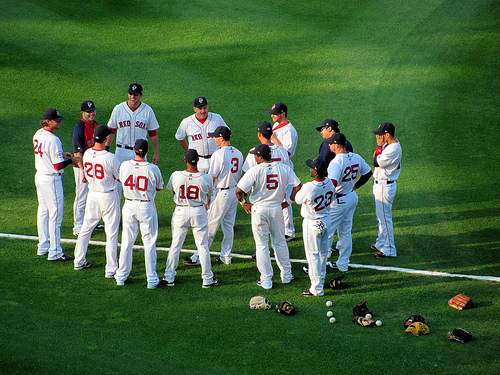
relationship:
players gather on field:
[38, 81, 405, 290] [13, 6, 480, 355]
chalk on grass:
[5, 228, 484, 290] [7, 10, 452, 372]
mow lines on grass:
[335, 13, 481, 260] [18, 34, 482, 366]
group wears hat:
[34, 80, 404, 299] [266, 103, 286, 115]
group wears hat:
[34, 80, 404, 299] [372, 121, 398, 136]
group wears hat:
[34, 80, 404, 299] [256, 119, 276, 138]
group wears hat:
[34, 80, 404, 299] [187, 145, 200, 161]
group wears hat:
[34, 80, 404, 299] [197, 97, 204, 104]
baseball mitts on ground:
[352, 289, 478, 349] [13, 20, 482, 360]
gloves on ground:
[405, 296, 468, 345] [13, 20, 482, 360]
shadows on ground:
[360, 220, 484, 285] [13, 20, 482, 360]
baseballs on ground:
[324, 299, 336, 324] [13, 20, 482, 360]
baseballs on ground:
[323, 298, 335, 328] [13, 20, 482, 360]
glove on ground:
[444, 291, 464, 309] [13, 20, 482, 360]